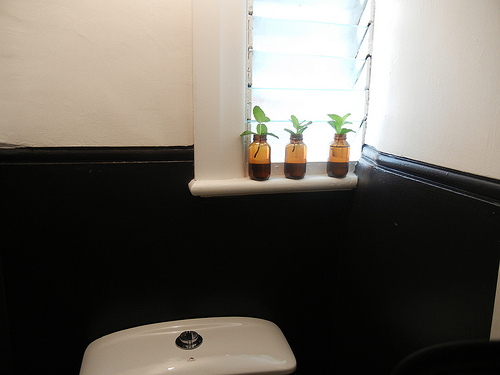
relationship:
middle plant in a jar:
[283, 114, 313, 135] [283, 133, 309, 180]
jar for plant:
[245, 132, 273, 184] [239, 104, 282, 139]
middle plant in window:
[285, 113, 314, 138] [248, 0, 361, 165]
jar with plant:
[245, 132, 273, 184] [239, 104, 282, 139]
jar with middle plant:
[283, 133, 309, 180] [283, 114, 313, 135]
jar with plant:
[327, 135, 350, 179] [327, 110, 358, 137]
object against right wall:
[488, 248, 499, 341] [360, 149, 499, 374]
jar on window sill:
[245, 132, 273, 184] [187, 179, 366, 198]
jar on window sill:
[283, 133, 309, 180] [187, 179, 366, 198]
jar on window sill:
[327, 135, 350, 179] [187, 179, 366, 198]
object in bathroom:
[382, 338, 498, 373] [1, 2, 500, 374]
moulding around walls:
[0, 145, 499, 209] [2, 2, 498, 374]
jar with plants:
[248, 134, 272, 181] [241, 104, 362, 138]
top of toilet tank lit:
[75, 313, 294, 374] [80, 316, 297, 375]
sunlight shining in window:
[248, 1, 404, 180] [248, 0, 361, 165]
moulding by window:
[193, 0, 246, 180] [248, 0, 361, 165]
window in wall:
[248, 0, 361, 165] [1, 1, 500, 180]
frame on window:
[193, 0, 242, 179] [248, 0, 361, 165]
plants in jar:
[241, 104, 362, 138] [248, 134, 272, 181]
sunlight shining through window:
[248, 1, 404, 180] [248, 0, 361, 165]